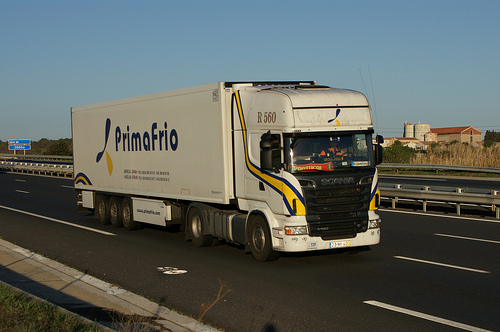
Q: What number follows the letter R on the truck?
A: 560.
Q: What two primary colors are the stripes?
A: Blue and yellow.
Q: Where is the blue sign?
A: Far left.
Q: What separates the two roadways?
A: Guardrails.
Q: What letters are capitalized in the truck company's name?
A: P and F.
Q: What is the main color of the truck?
A: White.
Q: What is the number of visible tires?
A: 5.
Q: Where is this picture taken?
A: Free way.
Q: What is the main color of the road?
A: Gray.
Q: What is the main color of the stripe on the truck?
A: Blue and yellow.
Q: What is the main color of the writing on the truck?
A: Blue.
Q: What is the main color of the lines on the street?
A: White.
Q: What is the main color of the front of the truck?
A: Black.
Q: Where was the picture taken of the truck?
A: The highway.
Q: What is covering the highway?
A: Asphalt.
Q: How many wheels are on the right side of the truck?
A: Five.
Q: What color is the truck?
A: White.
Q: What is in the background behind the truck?
A: A sign.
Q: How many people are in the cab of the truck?
A: One.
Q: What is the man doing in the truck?
A: Driving.